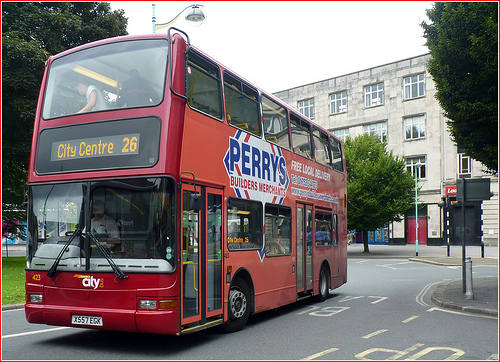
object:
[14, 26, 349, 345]
bus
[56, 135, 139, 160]
sign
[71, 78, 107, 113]
people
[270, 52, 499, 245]
building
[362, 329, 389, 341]
lines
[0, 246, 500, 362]
road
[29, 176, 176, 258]
windshield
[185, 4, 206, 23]
light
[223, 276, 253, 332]
wheel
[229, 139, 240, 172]
letters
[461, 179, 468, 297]
pole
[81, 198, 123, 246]
driver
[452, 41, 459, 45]
leaves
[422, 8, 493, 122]
tree